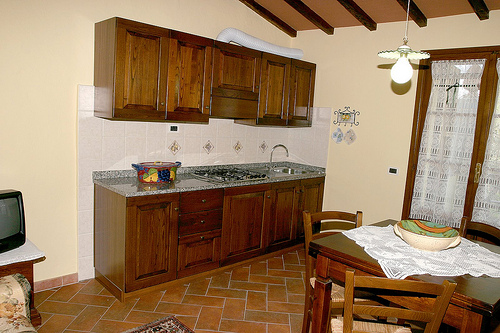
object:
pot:
[134, 157, 182, 183]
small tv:
[0, 185, 29, 254]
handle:
[130, 162, 139, 168]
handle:
[176, 158, 184, 168]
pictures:
[0, 2, 333, 140]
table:
[296, 210, 500, 326]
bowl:
[385, 215, 469, 253]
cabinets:
[92, 156, 177, 290]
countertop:
[84, 154, 329, 199]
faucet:
[270, 142, 290, 171]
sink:
[270, 160, 311, 178]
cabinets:
[289, 53, 320, 134]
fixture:
[372, 1, 441, 106]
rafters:
[266, 1, 304, 42]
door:
[114, 18, 168, 127]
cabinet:
[86, 14, 172, 124]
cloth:
[340, 263, 460, 332]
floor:
[32, 296, 287, 332]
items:
[333, 100, 361, 128]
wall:
[362, 50, 385, 203]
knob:
[472, 160, 484, 195]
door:
[398, 41, 476, 216]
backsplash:
[75, 78, 339, 286]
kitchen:
[0, 2, 498, 327]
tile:
[266, 257, 291, 276]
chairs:
[296, 203, 363, 240]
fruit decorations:
[141, 168, 155, 182]